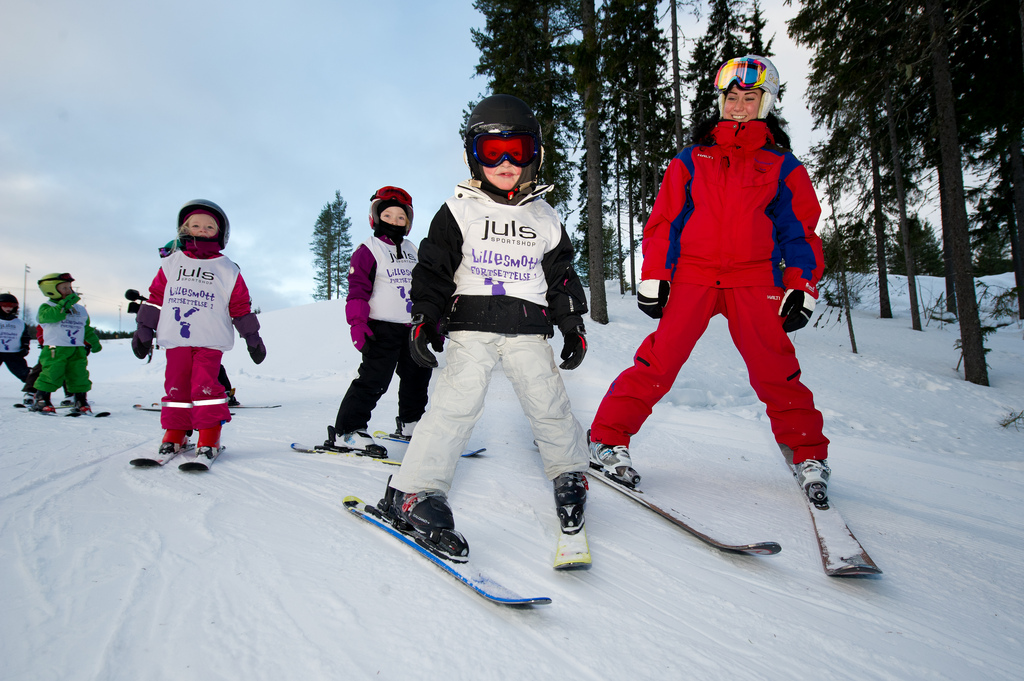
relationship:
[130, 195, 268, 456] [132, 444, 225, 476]
child wearing skis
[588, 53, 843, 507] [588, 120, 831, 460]
instructor wearing red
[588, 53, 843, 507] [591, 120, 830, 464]
instructor wearing red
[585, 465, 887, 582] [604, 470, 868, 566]
skis have snow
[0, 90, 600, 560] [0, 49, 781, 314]
children wearing helmets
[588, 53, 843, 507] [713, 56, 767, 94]
instructor wearing goggles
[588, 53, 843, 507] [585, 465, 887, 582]
instructor with skis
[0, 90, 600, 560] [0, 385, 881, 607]
children on skis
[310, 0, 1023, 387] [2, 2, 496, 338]
trees in front of sky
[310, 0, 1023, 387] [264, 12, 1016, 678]
trees in snow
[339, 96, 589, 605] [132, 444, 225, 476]
children has skis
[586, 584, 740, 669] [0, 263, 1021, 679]
lines of snow